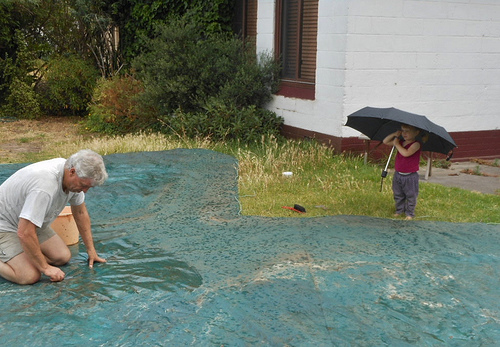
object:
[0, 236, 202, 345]
surface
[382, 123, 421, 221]
child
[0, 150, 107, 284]
man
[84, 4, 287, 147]
brush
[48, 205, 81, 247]
bucket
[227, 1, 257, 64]
window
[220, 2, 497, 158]
house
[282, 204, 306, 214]
brush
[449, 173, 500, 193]
floor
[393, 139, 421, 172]
shirt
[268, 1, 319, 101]
window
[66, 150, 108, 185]
hair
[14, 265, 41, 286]
knee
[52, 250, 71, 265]
knee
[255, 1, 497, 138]
wall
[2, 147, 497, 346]
plastic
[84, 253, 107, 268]
hand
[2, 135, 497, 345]
tarp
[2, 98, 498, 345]
ground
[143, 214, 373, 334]
surface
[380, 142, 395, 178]
handle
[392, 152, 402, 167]
red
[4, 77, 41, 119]
bushes